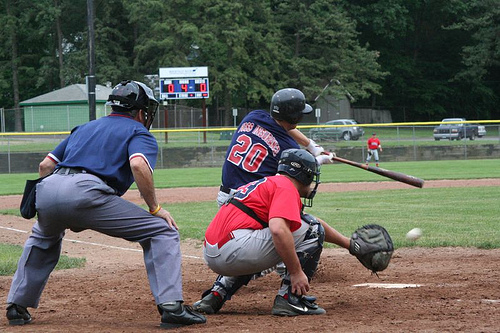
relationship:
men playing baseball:
[0, 67, 385, 320] [406, 229, 423, 241]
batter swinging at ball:
[217, 88, 336, 209] [403, 227, 421, 244]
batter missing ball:
[217, 88, 336, 209] [403, 227, 421, 244]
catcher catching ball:
[191, 145, 397, 318] [402, 215, 429, 248]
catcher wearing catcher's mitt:
[191, 145, 397, 318] [350, 223, 395, 279]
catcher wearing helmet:
[191, 145, 397, 318] [272, 147, 319, 189]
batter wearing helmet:
[228, 75, 308, 180] [258, 82, 310, 119]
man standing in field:
[366, 133, 383, 167] [0, 162, 499, 274]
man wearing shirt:
[360, 131, 382, 170] [202, 172, 307, 242]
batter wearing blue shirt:
[217, 88, 336, 209] [219, 106, 298, 189]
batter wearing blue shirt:
[217, 88, 336, 209] [44, 113, 159, 197]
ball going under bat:
[405, 227, 423, 241] [294, 135, 427, 190]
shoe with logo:
[270, 293, 326, 318] [286, 300, 308, 312]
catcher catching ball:
[193, 147, 394, 318] [379, 192, 434, 262]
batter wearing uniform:
[217, 88, 336, 209] [213, 109, 288, 186]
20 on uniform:
[226, 129, 263, 171] [213, 109, 288, 186]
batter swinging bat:
[217, 88, 336, 209] [320, 143, 437, 195]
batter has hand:
[217, 88, 336, 209] [313, 152, 338, 162]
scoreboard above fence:
[154, 63, 211, 106] [316, 122, 498, 158]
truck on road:
[433, 114, 480, 141] [0, 135, 500, 142]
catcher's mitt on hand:
[350, 223, 395, 279] [350, 236, 380, 257]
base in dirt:
[352, 279, 424, 294] [1, 179, 497, 330]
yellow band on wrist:
[3, 115, 498, 155] [145, 197, 164, 217]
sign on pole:
[313, 106, 323, 119] [313, 108, 323, 123]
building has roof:
[20, 78, 116, 135] [10, 76, 148, 114]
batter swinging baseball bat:
[217, 88, 336, 209] [320, 151, 425, 189]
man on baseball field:
[366, 133, 383, 167] [315, 161, 499, 234]